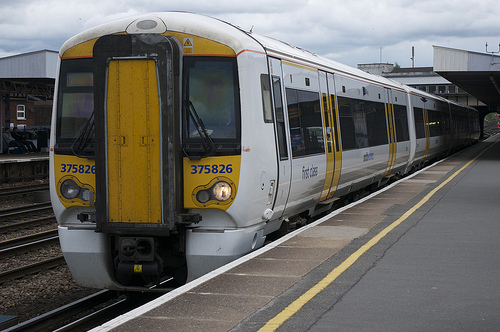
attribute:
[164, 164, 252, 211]
light — orange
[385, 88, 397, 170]
train — first-class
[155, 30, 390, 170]
train — white, yellow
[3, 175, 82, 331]
tracks — train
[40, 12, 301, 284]
lead car — black, yellow, white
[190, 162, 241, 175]
numbers — blue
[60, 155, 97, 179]
numbers — blue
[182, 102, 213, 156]
wiper — windshield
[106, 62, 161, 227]
door — yellow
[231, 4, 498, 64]
clouds — white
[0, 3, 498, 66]
clouds — white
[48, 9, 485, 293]
passenger train — white, yellow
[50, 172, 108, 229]
headlight — burned-out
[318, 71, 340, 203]
doors — passenger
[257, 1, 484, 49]
sky — blue